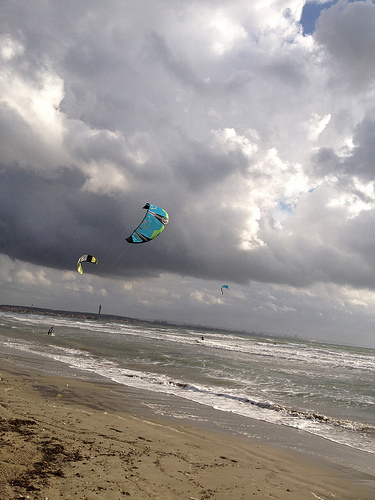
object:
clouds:
[0, 0, 375, 282]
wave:
[163, 378, 202, 401]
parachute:
[125, 201, 170, 251]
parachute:
[75, 253, 98, 273]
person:
[45, 327, 54, 339]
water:
[0, 306, 375, 483]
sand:
[0, 341, 375, 499]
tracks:
[48, 423, 92, 431]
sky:
[0, 0, 375, 349]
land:
[9, 307, 78, 317]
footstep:
[127, 465, 138, 472]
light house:
[97, 304, 103, 316]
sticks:
[49, 440, 59, 463]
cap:
[42, 427, 45, 430]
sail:
[219, 284, 230, 294]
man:
[198, 333, 209, 344]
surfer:
[200, 335, 207, 340]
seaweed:
[7, 421, 83, 498]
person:
[200, 331, 206, 339]